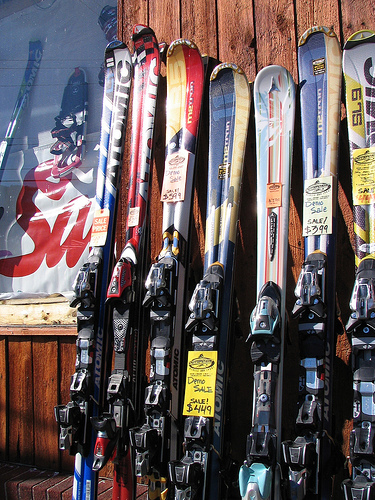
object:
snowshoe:
[46, 65, 88, 178]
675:
[89, 205, 123, 245]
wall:
[1, 0, 373, 498]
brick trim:
[4, 431, 134, 498]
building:
[1, 1, 372, 496]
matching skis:
[187, 61, 230, 472]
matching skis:
[296, 22, 334, 473]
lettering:
[187, 372, 215, 397]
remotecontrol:
[56, 15, 373, 498]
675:
[348, 84, 365, 131]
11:
[209, 87, 244, 122]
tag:
[302, 175, 333, 237]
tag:
[351, 146, 373, 206]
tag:
[157, 147, 189, 203]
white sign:
[9, 93, 74, 285]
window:
[3, 12, 105, 297]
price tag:
[261, 179, 283, 212]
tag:
[178, 347, 223, 425]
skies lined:
[56, 31, 374, 495]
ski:
[101, 45, 124, 247]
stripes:
[130, 22, 161, 498]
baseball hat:
[87, 204, 113, 249]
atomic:
[104, 59, 133, 193]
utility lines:
[1, 55, 105, 89]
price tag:
[89, 205, 116, 252]